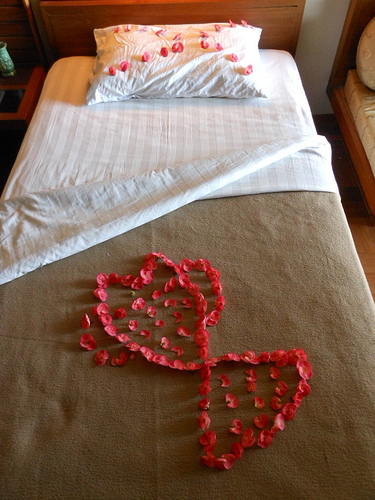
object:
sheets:
[0, 49, 340, 286]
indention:
[17, 385, 71, 452]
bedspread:
[0, 192, 375, 500]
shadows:
[171, 413, 200, 434]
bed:
[0, 50, 375, 499]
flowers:
[109, 19, 253, 76]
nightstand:
[0, 67, 46, 126]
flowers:
[80, 251, 312, 470]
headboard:
[34, 0, 306, 59]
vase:
[0, 43, 16, 76]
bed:
[326, 0, 375, 221]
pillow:
[86, 22, 268, 106]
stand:
[0, 6, 42, 70]